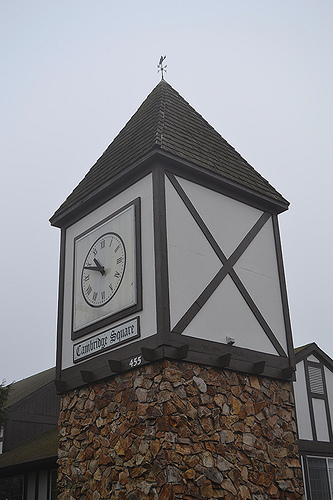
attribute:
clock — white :
[36, 197, 143, 313]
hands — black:
[86, 246, 105, 287]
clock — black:
[73, 207, 132, 308]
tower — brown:
[65, 61, 295, 196]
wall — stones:
[51, 344, 294, 498]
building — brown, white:
[291, 339, 331, 479]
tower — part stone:
[53, 72, 300, 495]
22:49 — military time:
[85, 244, 119, 280]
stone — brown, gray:
[61, 392, 297, 497]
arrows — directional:
[154, 64, 170, 73]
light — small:
[223, 334, 235, 347]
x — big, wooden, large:
[160, 168, 291, 357]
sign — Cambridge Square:
[68, 322, 141, 350]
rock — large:
[197, 416, 214, 432]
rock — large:
[191, 374, 209, 393]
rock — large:
[240, 429, 256, 446]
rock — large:
[215, 452, 233, 470]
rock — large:
[114, 417, 130, 433]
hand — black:
[81, 264, 104, 271]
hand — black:
[90, 257, 105, 276]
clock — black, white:
[79, 230, 125, 307]